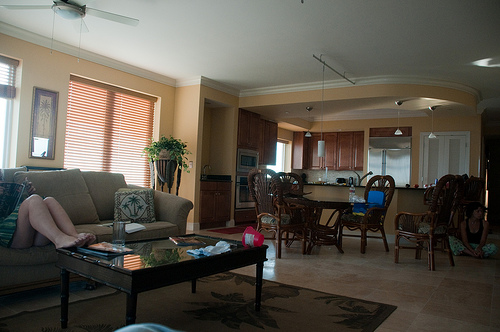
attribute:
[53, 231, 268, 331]
table — wooden, glass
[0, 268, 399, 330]
rug — large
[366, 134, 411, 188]
refrigerator — stainless steel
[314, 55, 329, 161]
light fixture — white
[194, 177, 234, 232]
cabinets — brown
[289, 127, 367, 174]
cabinets — brown, wooden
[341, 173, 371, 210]
bottle — plastic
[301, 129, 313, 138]
light — off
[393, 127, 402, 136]
light — off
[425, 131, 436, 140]
light — off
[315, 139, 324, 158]
light — off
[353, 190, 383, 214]
baby seat — blue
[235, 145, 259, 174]
microwave — white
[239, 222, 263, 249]
object — red